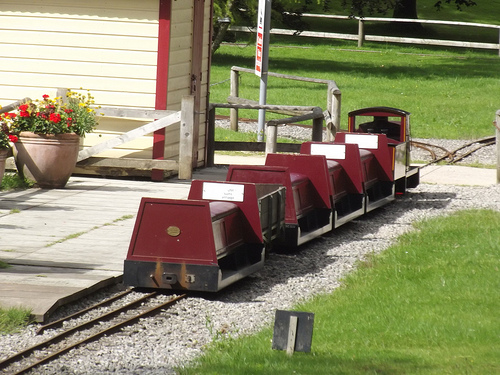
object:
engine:
[351, 115, 406, 185]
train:
[119, 102, 421, 293]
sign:
[202, 181, 245, 202]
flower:
[46, 111, 63, 124]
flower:
[6, 134, 19, 143]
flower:
[17, 103, 30, 113]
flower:
[53, 95, 62, 102]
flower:
[79, 102, 88, 109]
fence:
[208, 67, 339, 162]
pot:
[14, 128, 81, 185]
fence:
[221, 8, 494, 48]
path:
[32, 179, 471, 372]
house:
[4, 0, 215, 169]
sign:
[255, 7, 265, 70]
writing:
[254, 7, 260, 68]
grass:
[198, 0, 500, 371]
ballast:
[0, 293, 215, 373]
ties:
[78, 312, 117, 334]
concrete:
[0, 278, 59, 318]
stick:
[84, 119, 184, 151]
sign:
[252, 4, 275, 97]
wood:
[0, 0, 209, 172]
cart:
[114, 103, 419, 292]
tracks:
[0, 136, 500, 373]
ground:
[1, 6, 500, 367]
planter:
[7, 129, 85, 190]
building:
[3, 0, 217, 174]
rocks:
[159, 317, 189, 342]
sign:
[273, 306, 313, 356]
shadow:
[203, 186, 431, 306]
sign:
[251, 0, 267, 80]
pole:
[253, 0, 270, 143]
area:
[211, 0, 496, 138]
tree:
[206, 0, 293, 73]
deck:
[0, 173, 251, 325]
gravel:
[110, 294, 217, 366]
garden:
[21, 18, 495, 375]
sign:
[247, 0, 268, 87]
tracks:
[1, 280, 183, 371]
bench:
[202, 191, 252, 263]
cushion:
[207, 194, 240, 219]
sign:
[246, 2, 268, 79]